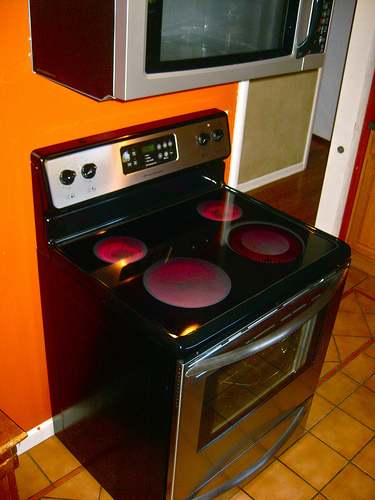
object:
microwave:
[27, 1, 323, 107]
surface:
[39, 156, 354, 363]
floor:
[0, 251, 373, 499]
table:
[2, 404, 30, 499]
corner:
[0, 406, 30, 461]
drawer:
[172, 390, 313, 499]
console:
[122, 133, 179, 175]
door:
[166, 274, 347, 498]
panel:
[28, 106, 231, 227]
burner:
[140, 252, 241, 309]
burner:
[222, 216, 304, 271]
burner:
[91, 227, 151, 269]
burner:
[192, 190, 251, 230]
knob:
[58, 168, 80, 189]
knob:
[78, 162, 100, 183]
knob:
[191, 128, 219, 148]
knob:
[210, 122, 223, 143]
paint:
[32, 424, 44, 437]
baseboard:
[16, 410, 61, 454]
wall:
[2, 3, 52, 435]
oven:
[31, 106, 354, 498]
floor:
[238, 140, 324, 229]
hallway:
[235, 0, 323, 228]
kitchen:
[4, 6, 362, 487]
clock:
[140, 140, 157, 154]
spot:
[32, 424, 44, 431]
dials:
[59, 162, 98, 184]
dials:
[193, 125, 230, 147]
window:
[198, 317, 320, 442]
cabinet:
[345, 125, 375, 274]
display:
[27, 115, 232, 213]